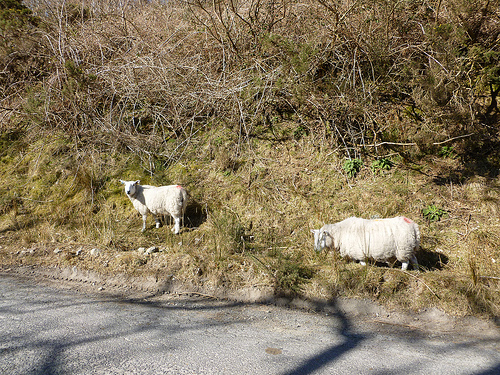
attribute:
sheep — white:
[124, 167, 430, 290]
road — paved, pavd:
[53, 290, 322, 373]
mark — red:
[401, 214, 415, 226]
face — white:
[114, 175, 144, 197]